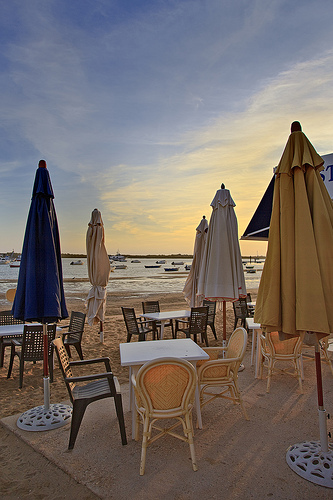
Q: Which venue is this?
A: This is a beach.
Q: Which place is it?
A: It is a beach.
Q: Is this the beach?
A: Yes, it is the beach.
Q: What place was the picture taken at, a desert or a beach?
A: It was taken at a beach.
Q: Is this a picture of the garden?
A: No, the picture is showing the beach.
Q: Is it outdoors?
A: Yes, it is outdoors.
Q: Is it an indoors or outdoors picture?
A: It is outdoors.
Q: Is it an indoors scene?
A: No, it is outdoors.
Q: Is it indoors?
A: No, it is outdoors.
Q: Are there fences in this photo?
A: No, there are no fences.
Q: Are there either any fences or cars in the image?
A: No, there are no fences or cars.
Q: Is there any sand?
A: Yes, there is sand.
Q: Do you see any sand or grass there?
A: Yes, there is sand.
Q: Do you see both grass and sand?
A: No, there is sand but no grass.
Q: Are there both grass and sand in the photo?
A: No, there is sand but no grass.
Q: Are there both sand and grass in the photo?
A: No, there is sand but no grass.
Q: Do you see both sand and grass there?
A: No, there is sand but no grass.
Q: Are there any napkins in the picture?
A: No, there are no napkins.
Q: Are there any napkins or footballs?
A: No, there are no napkins or footballs.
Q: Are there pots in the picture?
A: No, there are no pots.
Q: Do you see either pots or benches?
A: No, there are no pots or benches.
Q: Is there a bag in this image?
A: No, there are no bags.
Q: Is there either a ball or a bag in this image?
A: No, there are no bags or balls.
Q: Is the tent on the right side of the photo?
A: Yes, the tent is on the right of the image.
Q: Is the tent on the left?
A: No, the tent is on the right of the image.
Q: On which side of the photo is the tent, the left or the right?
A: The tent is on the right of the image.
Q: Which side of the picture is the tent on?
A: The tent is on the right of the image.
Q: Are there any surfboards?
A: No, there are no surfboards.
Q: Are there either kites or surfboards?
A: No, there are no surfboards or kites.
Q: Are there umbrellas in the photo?
A: Yes, there is an umbrella.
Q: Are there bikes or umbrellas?
A: Yes, there is an umbrella.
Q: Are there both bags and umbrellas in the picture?
A: No, there is an umbrella but no bags.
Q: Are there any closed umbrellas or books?
A: Yes, there is a closed umbrella.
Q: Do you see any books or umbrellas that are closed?
A: Yes, the umbrella is closed.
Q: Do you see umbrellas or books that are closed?
A: Yes, the umbrella is closed.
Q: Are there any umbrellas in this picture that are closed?
A: Yes, there is a closed umbrella.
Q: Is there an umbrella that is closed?
A: Yes, there is an umbrella that is closed.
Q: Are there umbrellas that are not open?
A: Yes, there is an closed umbrella.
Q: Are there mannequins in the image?
A: No, there are no mannequins.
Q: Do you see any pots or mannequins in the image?
A: No, there are no mannequins or pots.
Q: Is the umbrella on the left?
A: Yes, the umbrella is on the left of the image.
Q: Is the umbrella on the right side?
A: No, the umbrella is on the left of the image.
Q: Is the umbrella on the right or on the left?
A: The umbrella is on the left of the image.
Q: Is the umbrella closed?
A: Yes, the umbrella is closed.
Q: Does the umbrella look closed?
A: Yes, the umbrella is closed.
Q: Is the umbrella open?
A: No, the umbrella is closed.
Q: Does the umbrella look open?
A: No, the umbrella is closed.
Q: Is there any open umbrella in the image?
A: No, there is an umbrella but it is closed.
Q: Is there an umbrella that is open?
A: No, there is an umbrella but it is closed.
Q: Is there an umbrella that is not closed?
A: No, there is an umbrella but it is closed.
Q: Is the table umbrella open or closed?
A: The umbrella is closed.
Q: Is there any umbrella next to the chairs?
A: Yes, there is an umbrella next to the chairs.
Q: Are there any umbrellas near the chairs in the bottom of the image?
A: Yes, there is an umbrella near the chairs.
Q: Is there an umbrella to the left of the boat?
A: Yes, there is an umbrella to the left of the boat.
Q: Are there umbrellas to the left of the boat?
A: Yes, there is an umbrella to the left of the boat.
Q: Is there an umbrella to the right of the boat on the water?
A: No, the umbrella is to the left of the boat.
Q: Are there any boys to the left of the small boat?
A: No, there is an umbrella to the left of the boat.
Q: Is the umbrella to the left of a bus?
A: No, the umbrella is to the left of the boat.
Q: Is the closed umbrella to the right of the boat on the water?
A: No, the umbrella is to the left of the boat.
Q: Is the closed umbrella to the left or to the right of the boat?
A: The umbrella is to the left of the boat.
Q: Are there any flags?
A: No, there are no flags.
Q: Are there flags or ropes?
A: No, there are no flags or ropes.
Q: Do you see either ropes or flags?
A: No, there are no flags or ropes.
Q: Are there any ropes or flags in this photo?
A: No, there are no flags or ropes.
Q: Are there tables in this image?
A: Yes, there is a table.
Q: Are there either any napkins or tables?
A: Yes, there is a table.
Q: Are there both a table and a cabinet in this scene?
A: No, there is a table but no cabinets.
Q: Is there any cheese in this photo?
A: No, there is no cheese.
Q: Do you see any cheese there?
A: No, there is no cheese.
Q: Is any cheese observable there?
A: No, there is no cheese.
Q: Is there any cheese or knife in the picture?
A: No, there are no cheese or knives.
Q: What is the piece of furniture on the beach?
A: The piece of furniture is a table.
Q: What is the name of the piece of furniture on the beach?
A: The piece of furniture is a table.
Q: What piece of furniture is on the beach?
A: The piece of furniture is a table.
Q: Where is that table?
A: The table is on the beach.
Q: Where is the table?
A: The table is on the beach.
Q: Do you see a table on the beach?
A: Yes, there is a table on the beach.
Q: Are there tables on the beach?
A: Yes, there is a table on the beach.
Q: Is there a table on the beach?
A: Yes, there is a table on the beach.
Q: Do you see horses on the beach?
A: No, there is a table on the beach.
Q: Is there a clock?
A: No, there are no clocks.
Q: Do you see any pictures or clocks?
A: No, there are no clocks or pictures.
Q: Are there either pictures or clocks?
A: No, there are no clocks or pictures.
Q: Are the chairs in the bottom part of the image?
A: Yes, the chairs are in the bottom of the image.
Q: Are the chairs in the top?
A: No, the chairs are in the bottom of the image.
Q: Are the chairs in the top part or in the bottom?
A: The chairs are in the bottom of the image.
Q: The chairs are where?
A: The chairs are at the table.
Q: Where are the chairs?
A: The chairs are at the table.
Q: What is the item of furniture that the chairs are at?
A: The piece of furniture is a table.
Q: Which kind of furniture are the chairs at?
A: The chairs are at the table.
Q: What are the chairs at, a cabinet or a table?
A: The chairs are at a table.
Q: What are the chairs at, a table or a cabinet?
A: The chairs are at a table.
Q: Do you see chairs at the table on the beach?
A: Yes, there are chairs at the table.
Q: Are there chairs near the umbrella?
A: Yes, there are chairs near the umbrella.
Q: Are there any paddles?
A: No, there are no paddles.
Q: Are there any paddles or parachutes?
A: No, there are no paddles or parachutes.